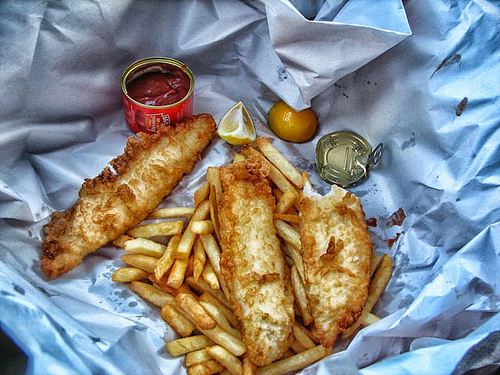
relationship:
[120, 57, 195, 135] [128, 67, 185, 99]
can has red substance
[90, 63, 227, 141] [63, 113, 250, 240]
can next to fish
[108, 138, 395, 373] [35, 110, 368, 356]
fries are on fish